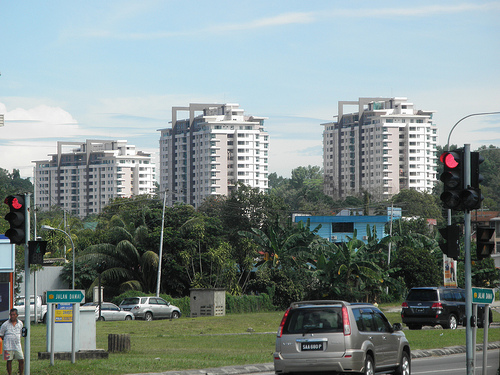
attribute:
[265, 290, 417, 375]
vehicle — grey, tan, mid-sized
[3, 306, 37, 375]
person — standing, waiting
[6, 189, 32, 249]
traffic light` — red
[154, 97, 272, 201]
building — large, white, multi-storied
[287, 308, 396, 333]
windows — darkened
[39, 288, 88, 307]
street sign — green, pointing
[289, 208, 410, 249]
structure — blue, stucco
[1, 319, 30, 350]
shirt — white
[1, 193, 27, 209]
light — red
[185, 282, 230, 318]
transformer box — grey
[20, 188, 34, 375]
pole — grey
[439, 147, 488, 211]
casing — black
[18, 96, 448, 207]
buildings — white, tall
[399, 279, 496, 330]
suv — dark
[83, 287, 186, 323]
cars — silver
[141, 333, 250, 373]
grass — green